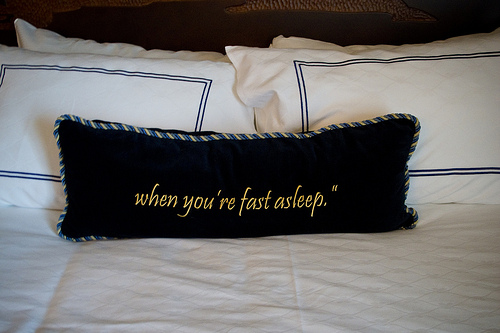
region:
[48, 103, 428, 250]
black long pillow on a bed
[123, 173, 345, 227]
gold words on a black pillow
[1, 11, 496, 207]
white pillows on a bed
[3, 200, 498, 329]
white sheets on a bed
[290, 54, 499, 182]
blue lines on a white pillowcase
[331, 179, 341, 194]
quotation marks on a black pillow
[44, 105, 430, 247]
black pillow in front of white pillows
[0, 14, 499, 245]
pillows on a bed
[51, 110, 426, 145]
blue and gold trim on a black pillow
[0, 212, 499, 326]
wrinkled white sheets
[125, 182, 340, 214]
yellow text on a pillow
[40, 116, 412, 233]
a black and blue pillow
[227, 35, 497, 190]
a white pillow with blue stripes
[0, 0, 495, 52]
a brown headboard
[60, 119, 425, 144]
blue and yellow frills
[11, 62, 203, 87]
blue stripes on a pillow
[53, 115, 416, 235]
a black pillow with text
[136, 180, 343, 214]
text on a pillow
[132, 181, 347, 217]
writing on a pillow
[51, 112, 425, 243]
a small pillow on bed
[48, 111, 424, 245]
pillow with gold writing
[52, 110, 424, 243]
pillow with blue and gold trimming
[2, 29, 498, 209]
two white and blue large pillows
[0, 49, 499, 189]
pillows with blue trimmings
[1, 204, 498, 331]
white blanket with designed lines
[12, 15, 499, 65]
two white pillows behind white and blue pillows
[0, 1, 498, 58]
a very dark back ground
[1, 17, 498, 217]
white pillows at head of bed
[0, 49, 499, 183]
double rectangle lines on pillows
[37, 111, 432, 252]
a black pillow with gold letters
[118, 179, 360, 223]
gold letters on a pillow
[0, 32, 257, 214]
a black and white pillow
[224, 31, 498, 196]
a black and white pillow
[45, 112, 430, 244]
a black pillow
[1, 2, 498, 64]
a wooden head board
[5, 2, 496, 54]
a brown, wooden headboard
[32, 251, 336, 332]
creases in a white comforter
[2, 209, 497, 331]
a white blanket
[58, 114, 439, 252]
Black pillow on the bed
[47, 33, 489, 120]
White pillows on the bed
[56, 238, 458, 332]
Comforter on the bed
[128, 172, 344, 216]
Gold letters on a pillow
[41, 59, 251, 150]
Strip on a pillow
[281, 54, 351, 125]
strips on a pillowcase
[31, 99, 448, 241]
strips on a pillow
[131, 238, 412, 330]
white blanket on the bed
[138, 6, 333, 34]
wood head board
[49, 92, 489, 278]
blue pillow on the bed